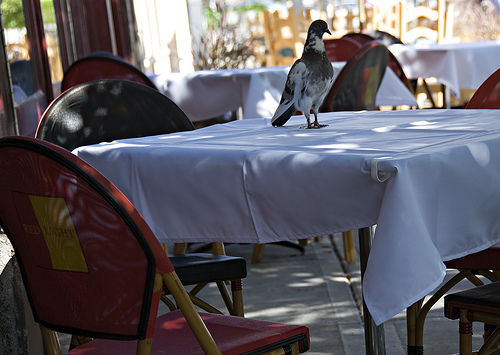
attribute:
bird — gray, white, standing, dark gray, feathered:
[271, 19, 337, 138]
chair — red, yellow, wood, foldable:
[2, 133, 311, 355]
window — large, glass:
[2, 0, 43, 109]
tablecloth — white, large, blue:
[69, 108, 497, 326]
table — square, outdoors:
[69, 109, 498, 354]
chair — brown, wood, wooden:
[444, 277, 498, 353]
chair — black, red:
[32, 74, 246, 317]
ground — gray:
[59, 225, 496, 354]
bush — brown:
[190, 24, 258, 67]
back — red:
[0, 135, 176, 341]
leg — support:
[356, 225, 384, 354]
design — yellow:
[9, 188, 90, 273]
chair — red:
[311, 38, 360, 62]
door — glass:
[33, 1, 67, 106]